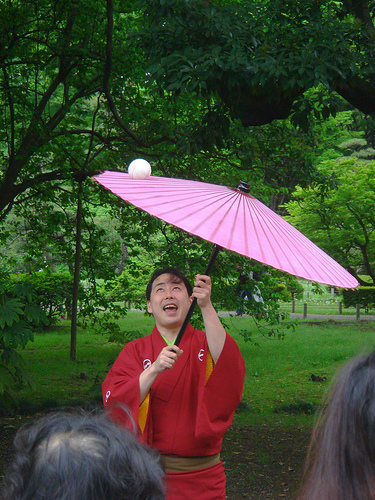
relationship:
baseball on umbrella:
[128, 157, 155, 182] [94, 168, 361, 364]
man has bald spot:
[10, 410, 160, 497] [28, 428, 99, 459]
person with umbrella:
[101, 267, 243, 498] [94, 168, 361, 364]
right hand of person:
[157, 342, 182, 376] [101, 267, 243, 498]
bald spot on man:
[28, 428, 99, 459] [10, 410, 160, 497]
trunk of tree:
[66, 267, 87, 359] [28, 96, 154, 358]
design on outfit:
[193, 343, 211, 364] [104, 324, 248, 497]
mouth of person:
[161, 300, 185, 318] [101, 267, 243, 498]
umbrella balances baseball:
[94, 168, 361, 364] [128, 157, 155, 182]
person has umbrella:
[101, 267, 243, 498] [94, 168, 361, 364]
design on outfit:
[141, 357, 153, 369] [104, 324, 248, 497]